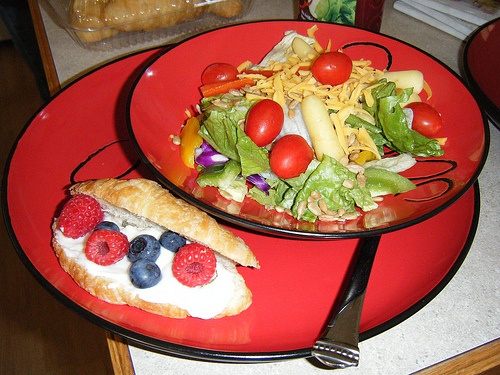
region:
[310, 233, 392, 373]
A silver fork under a plate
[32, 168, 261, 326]
A raspberry and blueberry treat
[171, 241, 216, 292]
A large red raspberry on bread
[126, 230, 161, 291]
Two blueberries on bread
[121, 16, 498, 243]
A red plate containing salad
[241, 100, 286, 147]
A small cherry tomato in a salad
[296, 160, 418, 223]
A piece of green lettuce in a salad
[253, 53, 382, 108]
Shredded cheese in a salad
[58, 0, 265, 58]
A plastic container with bread in it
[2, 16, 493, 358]
A two plate vegetable and fruit dish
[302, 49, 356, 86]
a red small tomato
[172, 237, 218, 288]
a fresh cranberry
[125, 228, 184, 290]
blue berries on top of cream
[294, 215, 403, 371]
a metal utensil under the plate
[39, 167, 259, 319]
a croissant with cream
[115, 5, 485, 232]
a salad bowl with lettuces and tomatoes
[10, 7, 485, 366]
a salad bowl with croissant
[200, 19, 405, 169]
a bunch of seeds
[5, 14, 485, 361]
one small bowl and a large red plate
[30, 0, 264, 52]
a clear box of coissants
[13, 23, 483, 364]
red plate and bowl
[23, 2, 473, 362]
plate and bowl have black trim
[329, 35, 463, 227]
salad bowl has black trim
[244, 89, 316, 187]
cherry tomatoes on top of salad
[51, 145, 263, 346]
croissant is split open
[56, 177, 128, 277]
red berries inside croissant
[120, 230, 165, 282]
blue berries inside croissant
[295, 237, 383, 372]
silverware on side of plate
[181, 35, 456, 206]
mixed salad in bowl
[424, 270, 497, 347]
counter is off white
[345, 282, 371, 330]
part of a handle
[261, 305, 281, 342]
part of a plate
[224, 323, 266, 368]
edge of a plate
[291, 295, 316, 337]
part of a plate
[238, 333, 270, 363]
part of a plate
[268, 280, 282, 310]
part of a plate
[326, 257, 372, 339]
part of a handle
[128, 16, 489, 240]
a red plate with a black border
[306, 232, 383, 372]
handle of a utensil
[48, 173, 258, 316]
a small croissant with cream cheese and fruits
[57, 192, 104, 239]
a raspberry on cream cheese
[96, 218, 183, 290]
four blueberries on cream cheese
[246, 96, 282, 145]
a cheery tomato in a salad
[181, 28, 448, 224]
a salad with veggies and cheese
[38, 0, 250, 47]
a plastic container with small croissants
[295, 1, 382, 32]
a bottle of red sauce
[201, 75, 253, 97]
a slice of carrot in a salad